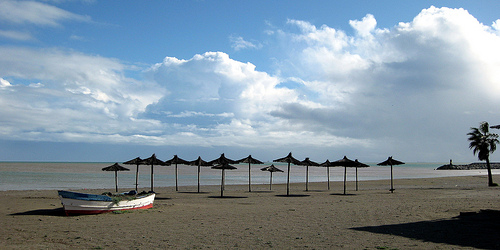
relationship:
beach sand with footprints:
[1, 215, 497, 247] [218, 183, 365, 244]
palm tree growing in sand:
[463, 122, 495, 188] [8, 185, 498, 240]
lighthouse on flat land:
[445, 155, 455, 164] [435, 160, 492, 171]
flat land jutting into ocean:
[435, 160, 492, 171] [9, 156, 489, 176]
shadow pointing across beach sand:
[337, 202, 497, 245] [1, 171, 498, 247]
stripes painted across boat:
[65, 201, 159, 207] [57, 190, 155, 216]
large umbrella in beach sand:
[103, 160, 127, 199] [1, 215, 497, 247]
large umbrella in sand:
[131, 156, 147, 190] [8, 185, 498, 240]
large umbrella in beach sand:
[144, 150, 165, 209] [1, 215, 497, 247]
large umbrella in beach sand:
[182, 152, 207, 187] [1, 215, 497, 247]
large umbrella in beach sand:
[187, 150, 208, 198] [1, 215, 497, 247]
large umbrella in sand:
[207, 150, 231, 203] [6, 171, 495, 240]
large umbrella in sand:
[232, 153, 269, 199] [6, 171, 495, 240]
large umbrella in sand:
[256, 156, 283, 198] [6, 171, 495, 240]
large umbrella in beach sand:
[269, 145, 299, 199] [1, 215, 497, 247]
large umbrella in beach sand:
[297, 156, 315, 194] [1, 215, 497, 247]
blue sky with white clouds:
[4, 3, 498, 163] [123, 30, 458, 133]